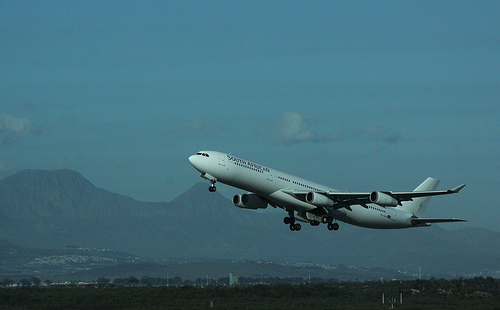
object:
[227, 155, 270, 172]
south american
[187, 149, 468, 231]
plane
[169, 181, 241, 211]
mountians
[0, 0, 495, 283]
background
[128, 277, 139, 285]
trees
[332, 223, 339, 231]
wheels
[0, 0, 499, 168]
sky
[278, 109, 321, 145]
cloud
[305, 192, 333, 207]
engines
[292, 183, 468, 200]
wing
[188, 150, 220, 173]
cockpit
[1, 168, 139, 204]
mountian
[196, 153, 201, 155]
windows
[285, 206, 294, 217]
landing gear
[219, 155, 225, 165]
door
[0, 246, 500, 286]
city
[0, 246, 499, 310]
distant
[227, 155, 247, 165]
south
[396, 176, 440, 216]
tail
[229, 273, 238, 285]
building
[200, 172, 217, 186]
landing gear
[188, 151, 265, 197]
front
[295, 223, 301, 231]
rear tires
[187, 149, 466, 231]
off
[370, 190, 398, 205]
e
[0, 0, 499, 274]
fog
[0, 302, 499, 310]
ground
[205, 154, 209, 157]
windshield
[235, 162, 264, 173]
row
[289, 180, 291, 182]
windows